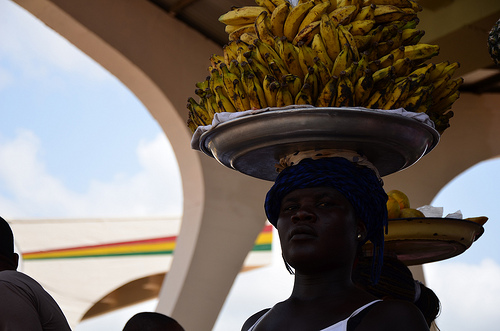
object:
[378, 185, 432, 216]
papayas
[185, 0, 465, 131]
bananas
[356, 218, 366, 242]
ear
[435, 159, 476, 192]
ground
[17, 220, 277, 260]
rainbow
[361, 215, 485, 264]
yellow tray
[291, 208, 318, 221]
girl nose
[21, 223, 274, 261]
band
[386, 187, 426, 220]
bananas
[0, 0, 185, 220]
clouds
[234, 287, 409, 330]
top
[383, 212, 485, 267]
plate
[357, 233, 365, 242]
earing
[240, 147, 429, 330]
person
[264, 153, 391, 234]
blue scarf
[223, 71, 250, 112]
banana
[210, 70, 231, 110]
banana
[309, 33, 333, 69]
banana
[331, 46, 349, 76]
banana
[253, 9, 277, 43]
banana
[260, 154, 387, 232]
wrap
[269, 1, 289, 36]
banana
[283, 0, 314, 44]
banana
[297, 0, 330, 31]
banana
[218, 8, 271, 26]
banana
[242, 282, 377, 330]
tank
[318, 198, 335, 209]
eye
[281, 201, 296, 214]
eye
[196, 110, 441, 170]
silver tray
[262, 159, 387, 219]
headscarf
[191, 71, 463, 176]
platter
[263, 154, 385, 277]
lady`s head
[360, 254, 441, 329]
braids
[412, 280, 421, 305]
white band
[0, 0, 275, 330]
archway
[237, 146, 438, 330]
girl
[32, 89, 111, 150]
blue sky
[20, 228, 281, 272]
flag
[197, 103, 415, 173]
tray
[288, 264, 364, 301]
neck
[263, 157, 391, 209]
scarf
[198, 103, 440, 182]
plate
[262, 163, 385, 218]
head wrap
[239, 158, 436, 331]
woman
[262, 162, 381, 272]
head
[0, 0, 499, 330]
background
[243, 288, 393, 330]
tank top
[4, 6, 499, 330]
photo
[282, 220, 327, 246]
lips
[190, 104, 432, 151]
cloth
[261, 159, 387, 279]
girl's head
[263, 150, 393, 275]
headgear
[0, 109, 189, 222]
cloud